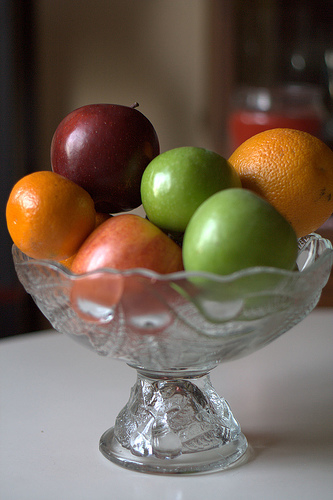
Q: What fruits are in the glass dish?
A: Apples and oranges.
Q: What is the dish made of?
A: Glass.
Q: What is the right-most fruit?
A: An orange.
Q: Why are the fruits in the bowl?
A: For people to eat.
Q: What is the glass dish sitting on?
A: A table.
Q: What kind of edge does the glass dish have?
A: Wavy or curved.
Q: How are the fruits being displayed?
A: They are in a glass dish.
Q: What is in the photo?
A: Food.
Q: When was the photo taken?
A: During the daytime.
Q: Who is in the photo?
A: No people.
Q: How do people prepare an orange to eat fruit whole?
A: By peeling.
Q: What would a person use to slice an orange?
A: Knife.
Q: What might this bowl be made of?
A: Crystal.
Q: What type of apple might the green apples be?
A: Granny smith.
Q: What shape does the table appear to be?
A: Round.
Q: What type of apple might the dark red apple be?
A: Red delicious.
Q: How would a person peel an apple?
A: With paring knife.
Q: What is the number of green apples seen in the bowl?
A: 2.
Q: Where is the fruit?
A: Bowl.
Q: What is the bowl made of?
A: Glass.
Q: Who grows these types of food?
A: Farmer.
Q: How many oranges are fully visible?
A: Two.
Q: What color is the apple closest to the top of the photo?
A: Red.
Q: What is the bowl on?
A: Table.